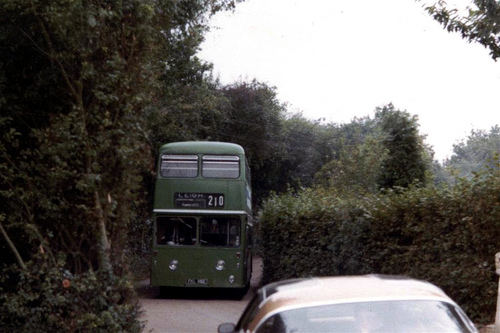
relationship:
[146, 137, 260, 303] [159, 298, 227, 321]
bus on ground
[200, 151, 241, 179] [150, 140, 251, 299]
blind on bus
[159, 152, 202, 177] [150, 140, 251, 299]
window on bus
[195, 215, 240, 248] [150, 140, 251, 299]
window on bus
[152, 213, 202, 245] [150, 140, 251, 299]
window on bus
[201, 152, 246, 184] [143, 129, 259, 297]
window on bus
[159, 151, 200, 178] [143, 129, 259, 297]
blind on bus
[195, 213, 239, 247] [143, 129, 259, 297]
window on bus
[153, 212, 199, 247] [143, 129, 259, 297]
window on bus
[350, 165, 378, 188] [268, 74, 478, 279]
leaves on trees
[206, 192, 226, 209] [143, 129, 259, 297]
writing on bus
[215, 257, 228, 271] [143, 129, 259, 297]
light on bus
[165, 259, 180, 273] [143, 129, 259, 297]
light on bus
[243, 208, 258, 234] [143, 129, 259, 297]
mirror on bus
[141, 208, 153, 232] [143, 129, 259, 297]
mirror on bus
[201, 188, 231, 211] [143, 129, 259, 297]
numbers on bus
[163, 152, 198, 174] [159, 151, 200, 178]
blind on blind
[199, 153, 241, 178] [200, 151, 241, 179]
blind on blind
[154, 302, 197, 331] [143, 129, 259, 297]
pavement under bus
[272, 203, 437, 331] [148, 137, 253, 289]
bush next to bus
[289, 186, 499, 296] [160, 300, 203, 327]
hedge by road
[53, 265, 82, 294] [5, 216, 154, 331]
flower on shrub